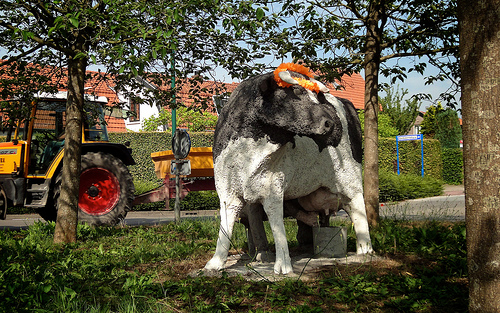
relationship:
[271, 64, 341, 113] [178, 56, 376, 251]
top of cow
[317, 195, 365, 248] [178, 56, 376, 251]
udder under cow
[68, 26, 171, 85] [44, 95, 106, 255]
tree has trunk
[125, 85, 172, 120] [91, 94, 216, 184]
roof of building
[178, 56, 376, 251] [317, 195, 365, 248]
cow with udder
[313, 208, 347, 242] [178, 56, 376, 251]
bucket under cow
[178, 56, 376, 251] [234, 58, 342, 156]
cow has head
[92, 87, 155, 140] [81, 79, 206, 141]
window in side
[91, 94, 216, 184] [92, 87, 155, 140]
building with window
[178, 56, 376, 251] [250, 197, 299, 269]
cow has leg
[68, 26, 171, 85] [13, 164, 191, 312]
tree in park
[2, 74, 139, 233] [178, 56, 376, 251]
tractor near cow